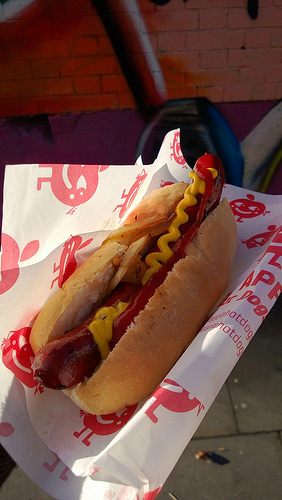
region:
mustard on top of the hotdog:
[87, 300, 129, 360]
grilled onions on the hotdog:
[106, 231, 151, 292]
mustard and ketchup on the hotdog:
[176, 167, 217, 238]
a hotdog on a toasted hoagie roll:
[29, 152, 236, 416]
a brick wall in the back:
[0, 1, 281, 115]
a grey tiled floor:
[158, 324, 281, 498]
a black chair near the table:
[133, 96, 244, 187]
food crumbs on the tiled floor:
[194, 449, 205, 460]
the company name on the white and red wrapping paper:
[1, 128, 281, 499]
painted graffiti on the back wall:
[0, 0, 198, 106]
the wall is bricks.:
[29, 11, 272, 95]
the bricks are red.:
[16, 9, 264, 89]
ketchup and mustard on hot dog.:
[82, 178, 233, 343]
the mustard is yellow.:
[86, 163, 231, 352]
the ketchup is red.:
[81, 151, 238, 346]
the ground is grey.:
[196, 336, 272, 493]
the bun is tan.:
[34, 168, 235, 379]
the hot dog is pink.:
[38, 151, 231, 380]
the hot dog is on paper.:
[3, 140, 274, 400]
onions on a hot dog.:
[69, 182, 225, 355]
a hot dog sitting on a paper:
[12, 180, 243, 418]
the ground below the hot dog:
[145, 316, 279, 495]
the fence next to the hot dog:
[2, 1, 280, 101]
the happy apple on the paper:
[35, 164, 106, 219]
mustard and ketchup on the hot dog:
[101, 172, 204, 339]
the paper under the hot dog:
[6, 164, 255, 498]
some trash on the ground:
[193, 448, 227, 464]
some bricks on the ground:
[17, 58, 110, 106]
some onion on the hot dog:
[113, 226, 144, 299]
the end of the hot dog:
[30, 352, 90, 399]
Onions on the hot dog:
[111, 235, 161, 296]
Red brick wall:
[3, 2, 278, 115]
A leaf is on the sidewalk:
[192, 442, 231, 468]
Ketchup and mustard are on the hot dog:
[81, 164, 229, 354]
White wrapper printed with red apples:
[3, 164, 280, 445]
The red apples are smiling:
[227, 186, 267, 224]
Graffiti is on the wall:
[69, 0, 280, 179]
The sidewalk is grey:
[176, 346, 279, 499]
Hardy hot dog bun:
[25, 176, 249, 419]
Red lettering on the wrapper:
[198, 249, 280, 363]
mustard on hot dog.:
[176, 197, 185, 225]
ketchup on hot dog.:
[58, 332, 87, 348]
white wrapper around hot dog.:
[127, 431, 173, 458]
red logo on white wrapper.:
[168, 393, 184, 407]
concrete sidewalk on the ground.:
[234, 464, 267, 490]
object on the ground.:
[192, 444, 221, 470]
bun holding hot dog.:
[165, 280, 190, 337]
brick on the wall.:
[45, 66, 94, 99]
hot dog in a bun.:
[72, 343, 82, 357]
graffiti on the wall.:
[105, 8, 147, 60]